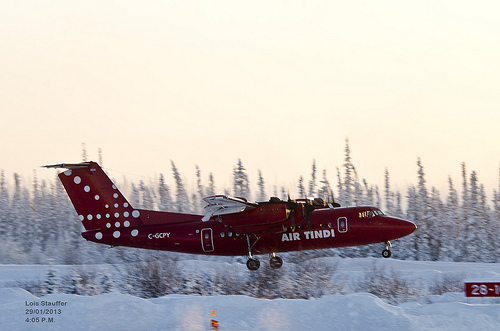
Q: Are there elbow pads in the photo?
A: No, there are no elbow pads.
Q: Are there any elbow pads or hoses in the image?
A: No, there are no elbow pads or hoses.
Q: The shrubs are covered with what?
A: The shrubs are covered with snow.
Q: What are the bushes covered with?
A: The shrubs are covered with snow.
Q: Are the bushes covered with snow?
A: Yes, the bushes are covered with snow.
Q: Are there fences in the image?
A: No, there are no fences.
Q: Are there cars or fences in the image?
A: No, there are no fences or cars.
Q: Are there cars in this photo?
A: No, there are no cars.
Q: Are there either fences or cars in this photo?
A: No, there are no cars or fences.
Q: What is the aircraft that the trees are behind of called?
A: The aircraft is an airplane.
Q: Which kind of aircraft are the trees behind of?
A: The trees are behind the plane.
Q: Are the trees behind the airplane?
A: Yes, the trees are behind the airplane.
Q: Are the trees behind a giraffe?
A: No, the trees are behind the airplane.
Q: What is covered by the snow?
A: The trees are covered by the snow.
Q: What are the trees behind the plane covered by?
A: The trees are covered by the snow.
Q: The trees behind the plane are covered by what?
A: The trees are covered by the snow.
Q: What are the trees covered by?
A: The trees are covered by the snow.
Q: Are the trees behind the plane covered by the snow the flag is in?
A: Yes, the trees are covered by the snow.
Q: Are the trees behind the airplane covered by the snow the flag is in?
A: Yes, the trees are covered by the snow.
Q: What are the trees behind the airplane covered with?
A: The trees are covered with snow.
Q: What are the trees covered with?
A: The trees are covered with snow.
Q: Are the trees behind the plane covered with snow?
A: Yes, the trees are covered with snow.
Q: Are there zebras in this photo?
A: No, there are no zebras.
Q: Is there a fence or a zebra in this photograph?
A: No, there are no zebras or fences.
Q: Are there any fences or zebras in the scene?
A: No, there are no zebras or fences.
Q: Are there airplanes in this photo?
A: Yes, there is an airplane.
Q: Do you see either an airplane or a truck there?
A: Yes, there is an airplane.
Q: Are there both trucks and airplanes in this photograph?
A: No, there is an airplane but no trucks.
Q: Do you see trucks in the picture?
A: No, there are no trucks.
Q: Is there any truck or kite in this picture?
A: No, there are no trucks or kites.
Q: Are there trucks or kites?
A: No, there are no trucks or kites.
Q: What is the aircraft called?
A: The aircraft is an airplane.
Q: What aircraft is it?
A: The aircraft is an airplane.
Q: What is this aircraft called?
A: This is an airplane.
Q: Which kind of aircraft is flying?
A: The aircraft is an airplane.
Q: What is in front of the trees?
A: The airplane is in front of the trees.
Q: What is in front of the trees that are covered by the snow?
A: The airplane is in front of the trees.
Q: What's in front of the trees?
A: The airplane is in front of the trees.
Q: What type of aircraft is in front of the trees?
A: The aircraft is an airplane.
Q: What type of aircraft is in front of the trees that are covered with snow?
A: The aircraft is an airplane.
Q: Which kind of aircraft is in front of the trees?
A: The aircraft is an airplane.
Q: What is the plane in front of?
A: The plane is in front of the trees.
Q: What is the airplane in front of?
A: The plane is in front of the trees.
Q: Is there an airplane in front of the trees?
A: Yes, there is an airplane in front of the trees.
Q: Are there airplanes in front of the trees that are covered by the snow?
A: Yes, there is an airplane in front of the trees.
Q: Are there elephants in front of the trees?
A: No, there is an airplane in front of the trees.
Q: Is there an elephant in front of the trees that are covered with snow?
A: No, there is an airplane in front of the trees.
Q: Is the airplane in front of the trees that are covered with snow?
A: Yes, the airplane is in front of the trees.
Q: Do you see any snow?
A: Yes, there is snow.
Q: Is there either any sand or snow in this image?
A: Yes, there is snow.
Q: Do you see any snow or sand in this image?
A: Yes, there is snow.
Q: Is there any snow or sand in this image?
A: Yes, there is snow.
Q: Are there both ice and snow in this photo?
A: No, there is snow but no ice.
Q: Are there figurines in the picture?
A: No, there are no figurines.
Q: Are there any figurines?
A: No, there are no figurines.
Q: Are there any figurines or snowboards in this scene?
A: No, there are no figurines or snowboards.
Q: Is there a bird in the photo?
A: No, there are no birds.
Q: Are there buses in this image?
A: No, there are no buses.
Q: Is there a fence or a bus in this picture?
A: No, there are no buses or fences.